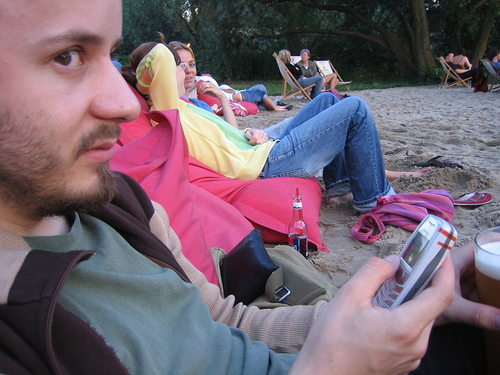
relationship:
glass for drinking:
[474, 223, 499, 374] [477, 241, 499, 375]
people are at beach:
[1, 1, 499, 374] [232, 84, 499, 287]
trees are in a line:
[120, 1, 496, 80] [120, 1, 499, 76]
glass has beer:
[474, 223, 499, 374] [475, 243, 499, 375]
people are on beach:
[1, 1, 499, 374] [232, 84, 499, 287]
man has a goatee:
[2, 1, 499, 374] [74, 123, 121, 208]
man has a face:
[2, 1, 499, 374] [3, 2, 142, 212]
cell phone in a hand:
[372, 214, 457, 306] [291, 252, 457, 374]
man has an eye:
[2, 1, 499, 374] [53, 49, 86, 68]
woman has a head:
[279, 50, 321, 98] [279, 50, 291, 62]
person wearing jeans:
[201, 80, 291, 112] [263, 94, 396, 211]